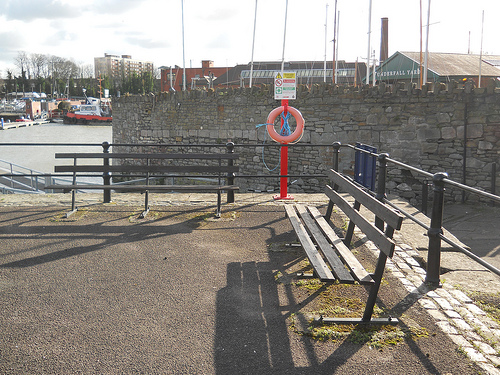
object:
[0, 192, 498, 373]
stone paving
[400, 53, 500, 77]
roof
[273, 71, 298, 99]
sign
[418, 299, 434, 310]
brick paver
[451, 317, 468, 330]
brick paver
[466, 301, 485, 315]
brick paver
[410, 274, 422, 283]
brick paver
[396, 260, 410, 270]
brick paver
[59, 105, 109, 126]
boat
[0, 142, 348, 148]
metal pole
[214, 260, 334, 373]
shadow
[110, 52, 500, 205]
building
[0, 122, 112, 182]
water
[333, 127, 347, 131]
brick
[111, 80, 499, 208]
stone wall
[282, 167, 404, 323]
bench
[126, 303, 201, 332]
concrete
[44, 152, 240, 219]
bench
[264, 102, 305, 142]
life saver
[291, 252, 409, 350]
grass patch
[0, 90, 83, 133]
harbor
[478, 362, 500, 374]
bricks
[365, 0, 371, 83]
sailboat beam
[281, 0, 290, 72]
sailboat beam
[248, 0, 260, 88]
sailboat beam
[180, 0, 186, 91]
sailboat beam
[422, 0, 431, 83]
sailboat beam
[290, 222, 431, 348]
grass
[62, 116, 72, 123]
tires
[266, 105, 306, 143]
life ring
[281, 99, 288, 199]
pole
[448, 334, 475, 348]
bricks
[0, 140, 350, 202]
fence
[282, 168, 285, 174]
red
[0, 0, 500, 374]
background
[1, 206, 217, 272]
shadow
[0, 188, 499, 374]
ground